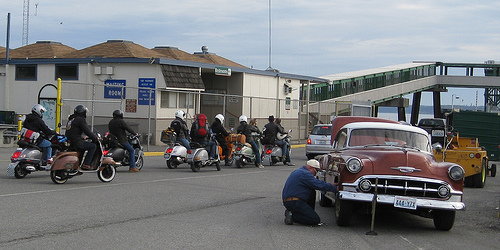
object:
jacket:
[60, 113, 98, 146]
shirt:
[280, 165, 335, 202]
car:
[308, 114, 469, 231]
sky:
[0, 0, 499, 108]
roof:
[0, 39, 251, 70]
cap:
[299, 158, 326, 174]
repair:
[280, 148, 387, 237]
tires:
[330, 196, 359, 228]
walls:
[0, 62, 303, 147]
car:
[305, 122, 335, 160]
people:
[105, 110, 145, 173]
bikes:
[97, 131, 145, 173]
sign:
[101, 78, 127, 100]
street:
[0, 145, 499, 250]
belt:
[279, 196, 304, 203]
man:
[278, 158, 340, 227]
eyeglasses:
[307, 167, 321, 175]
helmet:
[171, 110, 189, 121]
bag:
[224, 133, 247, 144]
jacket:
[167, 117, 190, 143]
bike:
[42, 130, 119, 185]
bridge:
[299, 60, 500, 123]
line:
[0, 166, 306, 198]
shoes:
[126, 164, 144, 173]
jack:
[363, 177, 384, 239]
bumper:
[340, 174, 469, 210]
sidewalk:
[0, 142, 500, 250]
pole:
[54, 76, 64, 134]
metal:
[442, 109, 500, 163]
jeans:
[280, 196, 321, 226]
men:
[162, 110, 191, 155]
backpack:
[190, 113, 212, 140]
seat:
[101, 131, 135, 146]